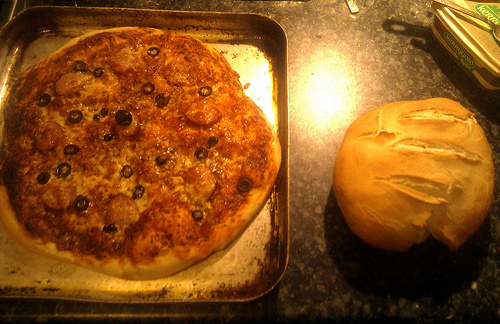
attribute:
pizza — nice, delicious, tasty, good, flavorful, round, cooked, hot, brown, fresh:
[0, 26, 281, 280]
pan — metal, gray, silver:
[3, 5, 291, 304]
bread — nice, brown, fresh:
[333, 97, 495, 252]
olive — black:
[92, 65, 106, 78]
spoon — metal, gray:
[437, 1, 499, 41]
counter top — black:
[2, 1, 498, 323]